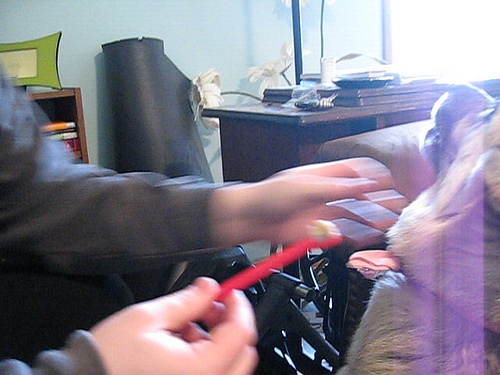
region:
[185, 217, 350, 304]
red object in a person's hand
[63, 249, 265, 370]
person's right hand holding an object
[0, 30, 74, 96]
green colored picture frame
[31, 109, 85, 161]
stack of four books on a shelf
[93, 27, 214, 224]
black object leaning on the wall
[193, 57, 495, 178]
large wooden desk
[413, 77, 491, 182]
person with long hair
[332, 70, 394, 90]
black dish on the desk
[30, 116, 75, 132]
orange book on the top of the stack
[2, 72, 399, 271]
person reaching with left arm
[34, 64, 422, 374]
picture taken indoors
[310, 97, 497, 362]
a dog is next to the person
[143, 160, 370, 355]
a man is holding a red straw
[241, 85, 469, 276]
a man is reaching for the dog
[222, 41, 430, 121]
a table in the background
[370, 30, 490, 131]
the sun is coming through the window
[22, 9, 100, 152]
a green frame on the bookcase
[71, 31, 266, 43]
the walls are light blue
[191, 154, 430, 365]
the man's hands are bare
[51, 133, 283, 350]
the man is wearing a gray shirt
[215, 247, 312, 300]
red object held on right hand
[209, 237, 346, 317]
red object held on right hand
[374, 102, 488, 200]
dog is backing away from man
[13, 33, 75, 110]
picture frame is lime green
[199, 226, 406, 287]
man is holding a toothbrush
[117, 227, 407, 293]
toothbrush is red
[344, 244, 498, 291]
dog is wearing a pink bandana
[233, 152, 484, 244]
man is moving his hand towards the dog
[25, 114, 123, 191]
books on the bookcase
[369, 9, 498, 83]
light reflection coming in window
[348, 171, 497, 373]
dog is tan color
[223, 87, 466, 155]
desk is made of wood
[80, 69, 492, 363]
the photo is blurry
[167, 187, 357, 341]
person holding a red object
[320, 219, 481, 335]
the dog is wearing a pink cloth around its neck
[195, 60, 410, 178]
a big brown desk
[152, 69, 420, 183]
the desk is made of wood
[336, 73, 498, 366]
the dog is beige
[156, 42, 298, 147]
tall white flowers in the background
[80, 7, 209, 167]
a roll of black material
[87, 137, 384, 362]
the persons hands are white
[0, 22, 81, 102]
a green picture frame